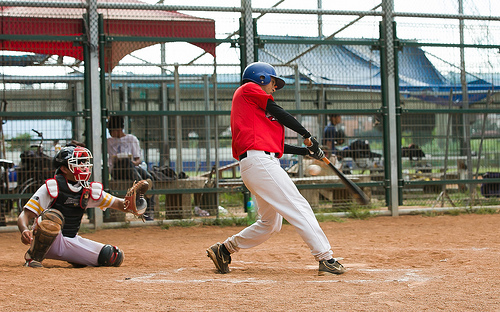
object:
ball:
[304, 163, 322, 177]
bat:
[302, 136, 370, 205]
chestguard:
[44, 172, 91, 239]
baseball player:
[204, 61, 352, 277]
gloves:
[303, 136, 323, 155]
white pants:
[221, 150, 336, 261]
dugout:
[0, 0, 498, 227]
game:
[16, 61, 371, 278]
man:
[320, 112, 345, 160]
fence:
[0, 0, 499, 227]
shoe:
[204, 242, 233, 276]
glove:
[120, 178, 152, 223]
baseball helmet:
[240, 61, 287, 91]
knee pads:
[22, 207, 67, 270]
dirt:
[0, 208, 499, 312]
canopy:
[253, 34, 499, 107]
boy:
[14, 141, 144, 270]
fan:
[105, 114, 144, 184]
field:
[0, 209, 499, 311]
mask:
[64, 145, 94, 190]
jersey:
[228, 81, 286, 162]